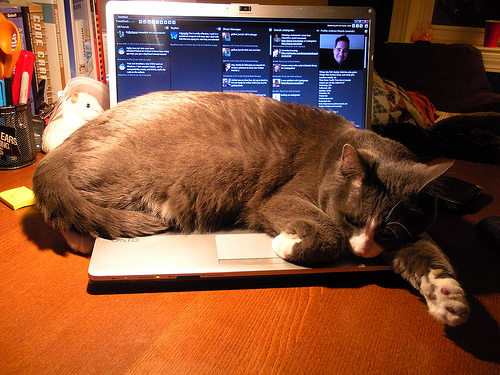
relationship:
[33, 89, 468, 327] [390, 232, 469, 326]
cat has paw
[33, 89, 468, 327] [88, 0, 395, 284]
cat laying on laptop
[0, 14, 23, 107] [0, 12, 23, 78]
scissor has handles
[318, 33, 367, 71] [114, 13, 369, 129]
picture on screen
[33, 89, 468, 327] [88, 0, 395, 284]
cat laying on computer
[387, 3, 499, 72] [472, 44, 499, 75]
window has a sill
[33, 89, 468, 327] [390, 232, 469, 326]
cat has left paw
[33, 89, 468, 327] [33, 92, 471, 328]
cat has fur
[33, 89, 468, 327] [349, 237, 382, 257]
cat has nose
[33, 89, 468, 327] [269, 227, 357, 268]
cat has paws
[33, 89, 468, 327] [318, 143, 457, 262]
cat has head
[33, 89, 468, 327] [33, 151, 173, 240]
cat has tail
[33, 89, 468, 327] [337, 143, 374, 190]
cat has right ear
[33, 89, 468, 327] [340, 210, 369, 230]
cat has eye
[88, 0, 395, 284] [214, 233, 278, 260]
laptop has touch pad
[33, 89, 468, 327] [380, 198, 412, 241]
cat has whiskers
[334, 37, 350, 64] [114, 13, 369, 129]
face on screen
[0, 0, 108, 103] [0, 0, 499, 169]
books are in background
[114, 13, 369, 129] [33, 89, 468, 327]
screen behind cat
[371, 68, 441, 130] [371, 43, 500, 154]
blanket on couch